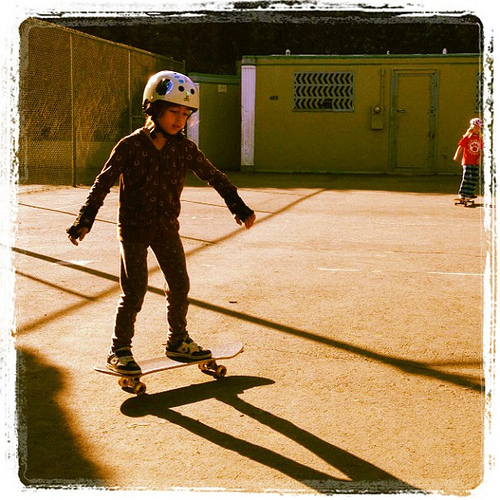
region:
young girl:
[56, 61, 227, 362]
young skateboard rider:
[66, 61, 256, 368]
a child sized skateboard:
[80, 348, 245, 401]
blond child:
[448, 104, 483, 209]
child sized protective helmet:
[135, 60, 200, 125]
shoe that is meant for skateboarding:
[105, 340, 142, 376]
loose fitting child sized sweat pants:
[112, 225, 194, 341]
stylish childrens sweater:
[75, 111, 242, 241]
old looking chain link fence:
[22, 20, 174, 195]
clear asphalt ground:
[22, 186, 480, 493]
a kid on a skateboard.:
[64, 65, 260, 398]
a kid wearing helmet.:
[130, 62, 212, 152]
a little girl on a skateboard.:
[449, 113, 483, 205]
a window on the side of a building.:
[289, 62, 364, 121]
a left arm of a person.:
[189, 136, 276, 232]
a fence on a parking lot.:
[21, 17, 202, 188]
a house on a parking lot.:
[233, 46, 480, 201]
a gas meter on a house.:
[366, 60, 391, 135]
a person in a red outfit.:
[450, 106, 481, 207]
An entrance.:
[388, 61, 440, 179]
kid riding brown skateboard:
[119, 77, 208, 392]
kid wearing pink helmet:
[130, 70, 219, 127]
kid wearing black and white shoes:
[115, 309, 221, 377]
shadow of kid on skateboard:
[135, 366, 335, 475]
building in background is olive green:
[287, 135, 386, 162]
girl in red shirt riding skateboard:
[446, 105, 481, 215]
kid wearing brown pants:
[117, 223, 214, 353]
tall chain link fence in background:
[41, 84, 151, 139]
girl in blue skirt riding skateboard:
[450, 104, 493, 211]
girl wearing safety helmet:
[459, 104, 494, 139]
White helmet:
[139, 67, 202, 117]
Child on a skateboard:
[66, 72, 261, 392]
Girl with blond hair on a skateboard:
[448, 113, 484, 210]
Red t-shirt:
[454, 134, 487, 166]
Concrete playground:
[30, 177, 486, 479]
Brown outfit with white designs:
[73, 128, 244, 333]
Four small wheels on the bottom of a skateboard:
[119, 357, 230, 397]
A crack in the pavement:
[252, 340, 473, 382]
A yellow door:
[388, 68, 446, 180]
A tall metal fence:
[36, 21, 188, 181]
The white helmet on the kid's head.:
[139, 67, 204, 109]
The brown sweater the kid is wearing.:
[92, 125, 229, 228]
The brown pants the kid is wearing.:
[108, 238, 196, 340]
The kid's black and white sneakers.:
[97, 341, 215, 373]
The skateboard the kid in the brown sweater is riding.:
[87, 341, 246, 374]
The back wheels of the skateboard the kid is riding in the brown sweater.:
[116, 374, 146, 391]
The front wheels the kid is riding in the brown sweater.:
[197, 356, 226, 373]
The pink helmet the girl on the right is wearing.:
[464, 119, 482, 126]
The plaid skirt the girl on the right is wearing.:
[458, 160, 485, 200]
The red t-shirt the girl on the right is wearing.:
[451, 130, 485, 161]